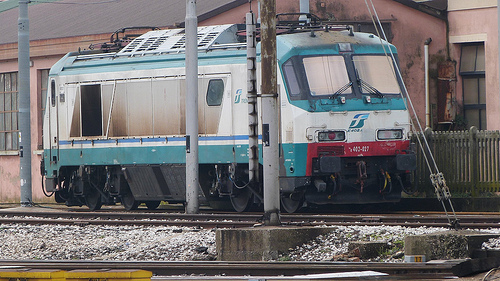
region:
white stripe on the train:
[44, 65, 309, 136]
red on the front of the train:
[300, 133, 433, 183]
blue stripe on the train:
[48, 127, 270, 151]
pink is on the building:
[0, 23, 76, 228]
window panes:
[1, 68, 40, 152]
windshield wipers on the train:
[323, 70, 403, 116]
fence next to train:
[431, 119, 493, 193]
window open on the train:
[73, 76, 133, 149]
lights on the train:
[294, 126, 416, 155]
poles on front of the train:
[6, 9, 401, 213]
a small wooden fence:
[411, 125, 499, 192]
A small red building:
[0, 1, 498, 202]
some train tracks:
[2, 204, 494, 279]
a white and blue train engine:
[41, 15, 423, 208]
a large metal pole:
[15, 0, 37, 202]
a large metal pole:
[183, 0, 199, 212]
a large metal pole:
[255, 0, 279, 228]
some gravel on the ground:
[2, 213, 499, 266]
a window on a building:
[0, 70, 19, 154]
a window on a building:
[36, 65, 51, 151]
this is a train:
[56, 23, 388, 205]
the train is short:
[42, 25, 395, 201]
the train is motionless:
[47, 23, 385, 209]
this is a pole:
[249, 0, 289, 101]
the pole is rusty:
[245, 2, 284, 94]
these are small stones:
[117, 229, 162, 257]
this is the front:
[285, 175, 364, 215]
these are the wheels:
[84, 173, 136, 208]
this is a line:
[418, 160, 464, 208]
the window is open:
[77, 83, 105, 138]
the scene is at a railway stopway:
[8, 7, 458, 233]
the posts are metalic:
[174, 31, 193, 213]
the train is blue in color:
[69, 30, 400, 167]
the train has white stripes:
[51, 27, 396, 182]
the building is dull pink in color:
[408, 7, 428, 127]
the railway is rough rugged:
[91, 221, 221, 271]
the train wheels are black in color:
[77, 166, 126, 199]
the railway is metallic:
[168, 250, 261, 280]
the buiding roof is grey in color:
[65, 0, 132, 27]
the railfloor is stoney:
[126, 222, 213, 265]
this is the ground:
[85, 223, 110, 238]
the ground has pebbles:
[78, 223, 139, 257]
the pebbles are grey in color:
[95, 227, 130, 244]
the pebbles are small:
[110, 229, 187, 254]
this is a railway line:
[43, 199, 230, 226]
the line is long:
[53, 210, 195, 224]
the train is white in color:
[233, 110, 239, 122]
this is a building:
[426, 12, 491, 107]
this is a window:
[447, 35, 484, 130]